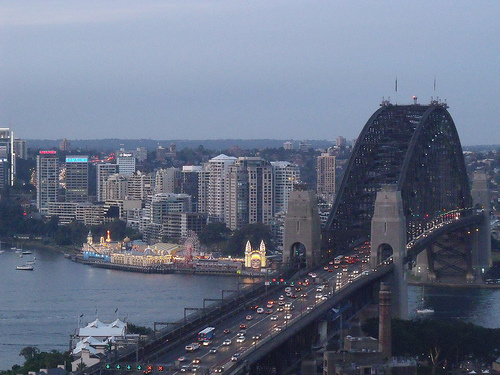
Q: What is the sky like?
A: Dark.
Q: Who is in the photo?
A: Nobody.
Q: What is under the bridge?
A: Water.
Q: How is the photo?
A: Clear.